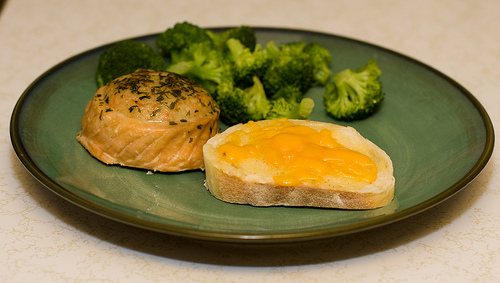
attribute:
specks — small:
[86, 53, 223, 141]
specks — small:
[92, 61, 216, 132]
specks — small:
[87, 56, 227, 133]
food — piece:
[64, 56, 241, 180]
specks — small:
[85, 61, 219, 136]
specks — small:
[94, 43, 232, 126]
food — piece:
[61, 53, 227, 189]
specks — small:
[82, 63, 224, 133]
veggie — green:
[322, 51, 395, 123]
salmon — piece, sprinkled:
[67, 61, 235, 188]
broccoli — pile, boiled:
[89, 14, 387, 134]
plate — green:
[9, 22, 497, 247]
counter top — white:
[1, 0, 497, 280]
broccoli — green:
[93, 20, 386, 122]